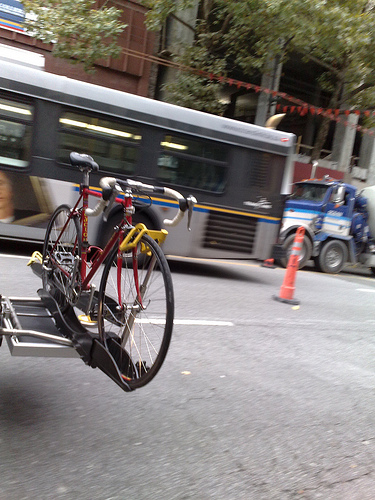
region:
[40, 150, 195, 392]
a red bicycle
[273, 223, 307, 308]
an orange traffic cone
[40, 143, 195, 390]
a bike hanging in the air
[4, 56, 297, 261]
a bus in motion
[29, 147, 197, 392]
a bike with a black seat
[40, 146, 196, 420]
a bike above the pavement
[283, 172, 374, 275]
a blue semi-truck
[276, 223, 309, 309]
a safety object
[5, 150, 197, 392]
a bike in a holder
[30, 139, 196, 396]
a bike in the city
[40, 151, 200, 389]
Bicycle with a red frame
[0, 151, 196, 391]
Bicycle on a vehicle bike rack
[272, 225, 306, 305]
Orange traffic cone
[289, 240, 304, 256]
Two silver reflective stripes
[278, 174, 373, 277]
Blue semi truck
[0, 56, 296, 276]
White and black transit bus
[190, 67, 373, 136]
Red flags held by strings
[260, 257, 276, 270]
Bottom of an orange traffic cone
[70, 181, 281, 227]
Yellow and blue stripe on a bus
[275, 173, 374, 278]
Blue semi truck with cement mixer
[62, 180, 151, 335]
red bike on road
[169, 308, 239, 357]
white line painted on road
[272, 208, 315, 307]
orange cone on road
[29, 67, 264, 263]
city bus passing by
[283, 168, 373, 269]
blue concrete mixer truck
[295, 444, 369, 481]
small cracks in paved road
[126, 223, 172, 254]
yellow lock on bike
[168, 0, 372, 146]
trees growing around street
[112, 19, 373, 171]
tall buildings across street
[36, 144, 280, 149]
row of windows on bus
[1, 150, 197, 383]
bicycle sits on bus bike rack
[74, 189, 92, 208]
bicycle is red color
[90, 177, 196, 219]
bicycle has arched handlebars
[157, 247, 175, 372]
rubber tire of bike wheel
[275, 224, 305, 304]
safety cone on road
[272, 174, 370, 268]
blue cement mixer truck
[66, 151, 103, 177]
black seat of bike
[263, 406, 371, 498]
cracks in tar road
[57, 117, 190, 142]
yellow light inside bus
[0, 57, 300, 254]
back of a bus; right of image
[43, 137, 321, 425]
Bicycle on the street.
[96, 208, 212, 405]
Wheel of the bicycle.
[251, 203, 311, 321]
Cone on the road.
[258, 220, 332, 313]
Orange cone on the road.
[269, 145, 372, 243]
cab of the truck.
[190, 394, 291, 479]
crack on the road.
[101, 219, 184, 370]
Spokes on the wheel.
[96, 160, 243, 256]
Handle on the bike.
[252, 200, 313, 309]
White part of the cone.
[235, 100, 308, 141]
Exhaust on the bus.